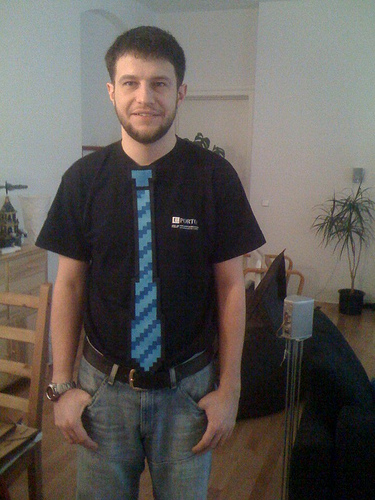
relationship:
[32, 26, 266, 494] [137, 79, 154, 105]
man has nose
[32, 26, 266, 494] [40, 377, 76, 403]
man has wristwatch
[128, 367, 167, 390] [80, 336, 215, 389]
buckle of belt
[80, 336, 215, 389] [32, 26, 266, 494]
belt on man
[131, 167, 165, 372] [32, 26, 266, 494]
tie of man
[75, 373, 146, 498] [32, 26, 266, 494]
leg of man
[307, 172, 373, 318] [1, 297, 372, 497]
houseplant on wooden floor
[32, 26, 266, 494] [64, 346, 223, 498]
man wearing jeans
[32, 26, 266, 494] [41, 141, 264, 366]
man wearing t-shirt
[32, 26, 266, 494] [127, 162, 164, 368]
man wearing tie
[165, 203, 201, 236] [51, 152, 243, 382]
logo on black t-shirt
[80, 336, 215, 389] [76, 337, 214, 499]
belt around jeans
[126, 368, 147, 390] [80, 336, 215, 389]
clip on belt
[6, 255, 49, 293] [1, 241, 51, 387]
drawer on chest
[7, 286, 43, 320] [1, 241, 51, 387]
drawer on chest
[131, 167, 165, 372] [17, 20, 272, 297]
tie on man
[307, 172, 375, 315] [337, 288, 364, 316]
houseplant on pot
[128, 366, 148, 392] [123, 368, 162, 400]
hinge on belt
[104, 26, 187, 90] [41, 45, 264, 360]
hair on man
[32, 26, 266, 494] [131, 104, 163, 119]
man has moustache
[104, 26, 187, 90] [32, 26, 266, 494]
hair belonging to man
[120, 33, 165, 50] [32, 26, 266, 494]
hair belonging to man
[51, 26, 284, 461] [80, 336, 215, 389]
man wearing belt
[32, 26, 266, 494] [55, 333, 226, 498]
man wearing jeans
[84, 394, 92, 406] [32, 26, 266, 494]
thumb belonging to man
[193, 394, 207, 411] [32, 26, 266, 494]
thumb belonging to man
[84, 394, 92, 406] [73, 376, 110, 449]
thumb hooked in pocket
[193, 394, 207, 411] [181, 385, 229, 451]
thumb hooked in pocket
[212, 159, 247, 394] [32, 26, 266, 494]
arm belonging to man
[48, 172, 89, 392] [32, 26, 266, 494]
arm belonging to man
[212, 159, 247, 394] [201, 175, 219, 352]
arm hanging down side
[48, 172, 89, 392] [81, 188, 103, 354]
arm hanging down side